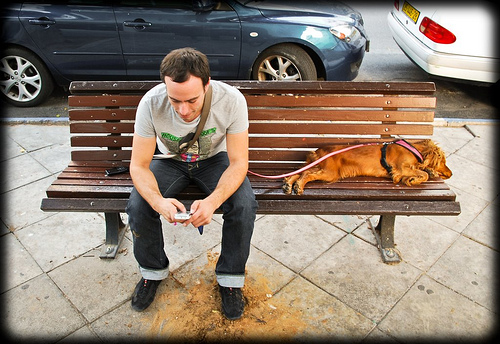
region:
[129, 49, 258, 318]
man sitting on bench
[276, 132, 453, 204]
dog sleeping on bench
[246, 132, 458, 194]
dog has pink leash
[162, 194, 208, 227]
man is texting on phone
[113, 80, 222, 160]
man is wearing messenger bag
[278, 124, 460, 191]
dog is red orange color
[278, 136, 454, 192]
dog is medium size with medium length fur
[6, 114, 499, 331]
concrete tile sidewalk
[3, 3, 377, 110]
blue car parked on curb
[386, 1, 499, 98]
white car parked on curb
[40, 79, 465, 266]
wood and metal bench on sidewalk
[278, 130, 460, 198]
brown dog lying on bench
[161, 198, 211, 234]
man holding white object in his hands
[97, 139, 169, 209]
black phone on bench beside man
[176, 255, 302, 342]
man's left foot resting in dirt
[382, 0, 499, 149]
white vehicle near curb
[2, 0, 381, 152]
blue-grey vehicle near curb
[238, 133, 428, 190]
pink restraint and leash attached to dog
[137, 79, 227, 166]
brown strap around man's shoulder and waist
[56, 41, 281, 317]
MAN SITTING ON A BENCH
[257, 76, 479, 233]
A DOG SLEEPING ON A BENCH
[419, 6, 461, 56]
A REAR RED BRAKE LIGHT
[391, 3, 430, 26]
A LICENSE PLATE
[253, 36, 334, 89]
A FRONT TIRE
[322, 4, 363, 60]
CAR HEADLIGHTS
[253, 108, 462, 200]
DOG ON A PINK LEASH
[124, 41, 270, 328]
MAN LOOKING AT HIS CELL PHONE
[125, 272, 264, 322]
PAIR OF BLACK SNEAKERS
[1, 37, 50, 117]
REAR TIRE HUB CAP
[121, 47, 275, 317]
Man sitting on bench with dog.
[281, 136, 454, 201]
Man's brown dog on leash.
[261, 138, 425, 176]
Dog's long red leash.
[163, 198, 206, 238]
Man holding a cellphone.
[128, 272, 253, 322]
Man wearing black tennis shoes.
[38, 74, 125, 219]
Brown slats on wood bench.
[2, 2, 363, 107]
Blue car in traffic behind man on bench.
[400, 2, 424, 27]
Yellow tag on white car's rear bumper.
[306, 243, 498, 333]
Dirty tile like concrete on sidewalk.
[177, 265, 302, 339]
Reddish brown dirt under man's foot.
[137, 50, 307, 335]
man is texting on his phone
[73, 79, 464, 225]
there is a brown bench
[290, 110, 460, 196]
dog is taking a nap on the bench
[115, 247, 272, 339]
man's jeans are rolled up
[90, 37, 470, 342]
man and dog sitting on the bench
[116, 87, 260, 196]
man has book bag strap on one shoulder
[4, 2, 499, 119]
two cars behind the bench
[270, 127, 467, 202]
dog is on a leash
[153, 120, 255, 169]
man is wearing a graphic tee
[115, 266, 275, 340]
black shoes